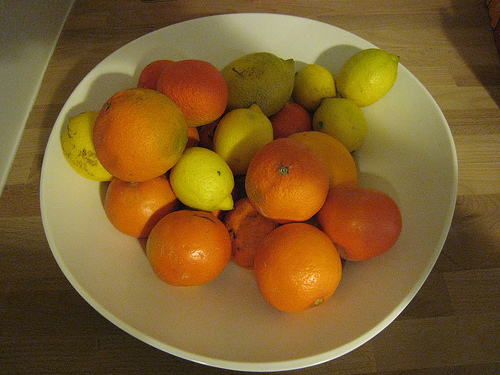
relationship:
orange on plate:
[146, 209, 232, 290] [39, 14, 460, 374]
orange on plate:
[93, 87, 189, 181] [39, 14, 460, 374]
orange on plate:
[246, 137, 329, 224] [39, 14, 460, 374]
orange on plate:
[252, 220, 342, 313] [39, 14, 460, 374]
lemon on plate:
[335, 49, 398, 107] [39, 14, 460, 374]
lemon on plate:
[169, 147, 234, 212] [39, 14, 460, 374]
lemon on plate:
[310, 96, 366, 153] [39, 14, 460, 374]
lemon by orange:
[169, 147, 234, 212] [246, 137, 329, 224]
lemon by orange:
[169, 147, 234, 212] [93, 87, 189, 181]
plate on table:
[39, 14, 460, 374] [0, 1, 498, 374]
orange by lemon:
[93, 87, 189, 181] [335, 49, 398, 107]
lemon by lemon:
[335, 49, 398, 107] [169, 147, 234, 212]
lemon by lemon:
[169, 147, 234, 212] [310, 96, 366, 153]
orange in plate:
[93, 87, 189, 181] [39, 14, 460, 374]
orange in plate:
[246, 137, 329, 224] [39, 14, 460, 374]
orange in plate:
[146, 209, 232, 290] [39, 14, 460, 374]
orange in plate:
[252, 220, 342, 313] [39, 14, 460, 374]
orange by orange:
[246, 137, 329, 224] [93, 87, 189, 181]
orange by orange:
[93, 87, 189, 181] [246, 137, 329, 224]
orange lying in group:
[93, 87, 189, 181] [89, 51, 405, 312]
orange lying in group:
[142, 204, 232, 287] [89, 51, 405, 312]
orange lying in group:
[244, 135, 332, 219] [89, 51, 405, 312]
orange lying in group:
[252, 220, 342, 313] [89, 51, 405, 312]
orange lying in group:
[317, 180, 403, 261] [89, 51, 405, 312]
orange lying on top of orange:
[93, 87, 189, 181] [103, 171, 179, 240]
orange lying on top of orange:
[93, 87, 189, 181] [134, 54, 177, 93]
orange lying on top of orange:
[244, 135, 332, 219] [221, 196, 283, 270]